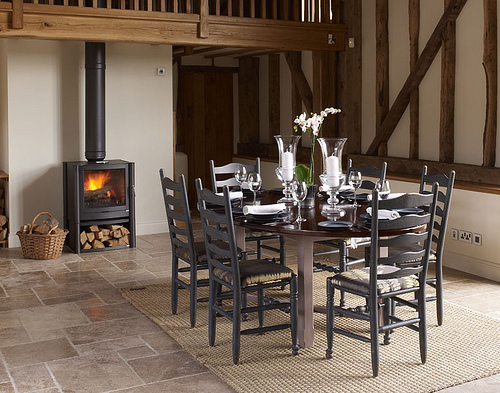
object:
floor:
[1, 288, 117, 393]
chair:
[192, 176, 300, 366]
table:
[196, 186, 432, 349]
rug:
[115, 258, 499, 393]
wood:
[90, 239, 106, 250]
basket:
[15, 211, 69, 260]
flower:
[292, 106, 342, 189]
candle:
[281, 148, 294, 182]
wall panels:
[479, 0, 500, 168]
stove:
[61, 159, 137, 255]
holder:
[271, 134, 304, 209]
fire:
[83, 169, 123, 207]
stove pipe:
[80, 39, 109, 164]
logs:
[35, 222, 50, 234]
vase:
[299, 185, 316, 211]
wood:
[372, 1, 391, 157]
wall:
[234, 0, 500, 282]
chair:
[157, 167, 247, 330]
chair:
[207, 156, 286, 292]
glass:
[234, 166, 249, 210]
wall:
[3, 37, 178, 250]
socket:
[472, 232, 483, 245]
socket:
[458, 230, 473, 245]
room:
[0, 0, 500, 393]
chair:
[363, 163, 456, 334]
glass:
[246, 171, 263, 206]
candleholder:
[316, 136, 349, 221]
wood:
[91, 186, 115, 197]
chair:
[324, 180, 441, 378]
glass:
[288, 180, 309, 225]